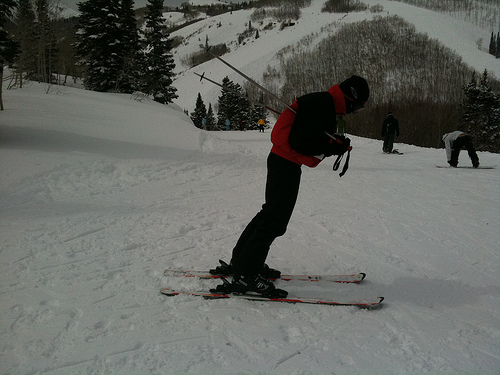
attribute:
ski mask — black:
[339, 76, 372, 111]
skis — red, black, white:
[163, 270, 387, 307]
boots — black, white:
[229, 266, 287, 299]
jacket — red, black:
[270, 78, 348, 168]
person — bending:
[440, 128, 484, 169]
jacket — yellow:
[257, 118, 267, 128]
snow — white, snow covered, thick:
[1, 128, 498, 374]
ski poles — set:
[197, 37, 339, 156]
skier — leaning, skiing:
[231, 76, 370, 299]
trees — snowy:
[77, 1, 180, 105]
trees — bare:
[269, 17, 485, 138]